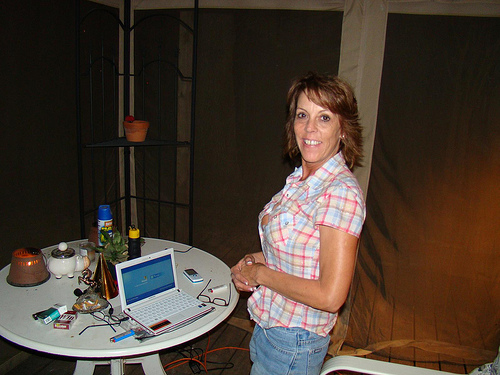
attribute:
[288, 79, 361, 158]
hair — brown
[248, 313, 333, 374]
jeans — blue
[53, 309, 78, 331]
cigarette pack — pictured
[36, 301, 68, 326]
cigarette pack — pictured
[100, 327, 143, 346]
blue lighter — light blue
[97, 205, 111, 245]
can — aerosol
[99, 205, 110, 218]
top — blue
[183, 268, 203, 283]
cellphone — small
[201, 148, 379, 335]
shirt — red, blue, striped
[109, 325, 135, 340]
lighter — blue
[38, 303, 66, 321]
cigarettes — pictured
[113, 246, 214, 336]
laptop — white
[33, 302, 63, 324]
cigarettes — boxed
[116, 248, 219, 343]
computer — open, white, netbook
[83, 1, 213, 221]
stand — black wire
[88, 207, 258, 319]
phone — candy bar style, cell phone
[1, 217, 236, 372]
white table — small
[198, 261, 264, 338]
glasses — reading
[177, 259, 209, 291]
cellphone — white 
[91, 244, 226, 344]
computer laptop — white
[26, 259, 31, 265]
candle — lit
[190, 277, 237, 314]
glasses — black, framed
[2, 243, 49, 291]
candle — bug repellent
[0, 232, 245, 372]
table — white, round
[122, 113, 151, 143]
pot — clay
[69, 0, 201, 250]
shelf — black